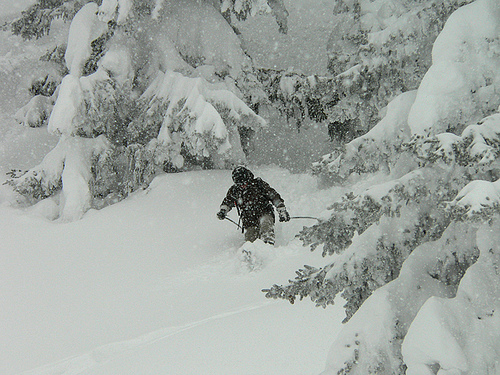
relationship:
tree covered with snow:
[260, 0, 497, 371] [257, 2, 496, 372]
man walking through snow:
[217, 164, 290, 244] [0, 0, 499, 372]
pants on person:
[243, 200, 381, 305] [226, 165, 289, 237]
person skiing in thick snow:
[217, 165, 289, 246] [58, 257, 190, 324]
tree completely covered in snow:
[284, 56, 498, 186] [8, 100, 472, 374]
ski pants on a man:
[214, 131, 308, 273] [217, 164, 290, 244]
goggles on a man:
[230, 168, 252, 185] [214, 161, 292, 256]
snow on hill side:
[37, 200, 219, 360] [0, 143, 139, 294]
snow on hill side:
[0, 0, 499, 372] [53, 209, 165, 344]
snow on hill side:
[99, 276, 236, 366] [33, 188, 158, 359]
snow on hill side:
[239, 298, 274, 340] [55, 229, 153, 355]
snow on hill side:
[2, 115, 492, 372] [7, 179, 499, 371]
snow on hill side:
[10, 190, 275, 374] [38, 188, 154, 324]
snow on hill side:
[164, 222, 236, 259] [41, 168, 161, 331]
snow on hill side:
[55, 250, 162, 326] [165, 172, 217, 207]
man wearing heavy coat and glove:
[217, 164, 290, 244] [277, 213, 289, 222]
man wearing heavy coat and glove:
[217, 164, 290, 244] [216, 210, 227, 218]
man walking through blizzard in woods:
[217, 164, 290, 244] [2, 2, 497, 372]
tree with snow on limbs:
[12, 14, 212, 224] [302, 167, 482, 297]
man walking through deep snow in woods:
[217, 164, 290, 244] [2, 2, 497, 372]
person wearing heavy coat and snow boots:
[217, 165, 289, 246] [212, 164, 296, 293]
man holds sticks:
[199, 163, 299, 245] [216, 204, 333, 239]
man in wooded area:
[217, 164, 290, 244] [0, 0, 499, 373]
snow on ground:
[165, 245, 261, 328] [6, 174, 395, 366]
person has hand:
[217, 164, 289, 266] [278, 212, 288, 222]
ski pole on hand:
[278, 215, 323, 222] [278, 212, 288, 222]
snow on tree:
[130, 213, 210, 301] [101, 8, 231, 161]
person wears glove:
[217, 165, 289, 246] [276, 211, 291, 222]